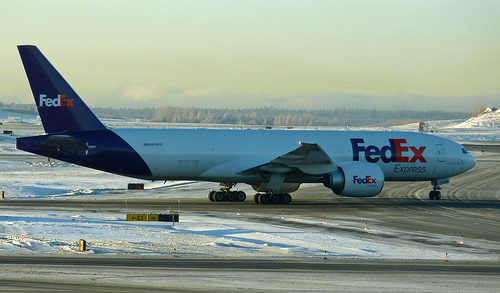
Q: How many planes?
A: One.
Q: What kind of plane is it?
A: A fed fex plane.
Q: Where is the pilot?
A: In the plane.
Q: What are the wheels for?
A: To land.